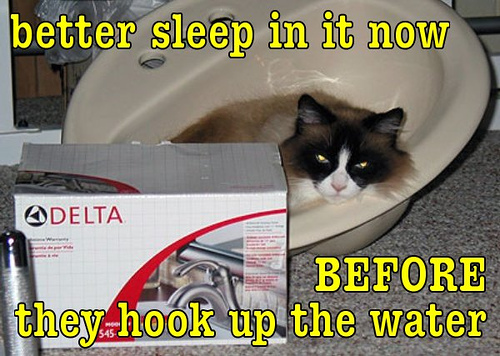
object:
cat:
[166, 91, 420, 206]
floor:
[1, 128, 498, 354]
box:
[13, 139, 293, 349]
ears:
[360, 106, 406, 132]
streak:
[335, 142, 354, 169]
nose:
[330, 170, 349, 193]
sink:
[60, 1, 495, 257]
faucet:
[165, 281, 229, 324]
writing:
[10, 10, 139, 54]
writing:
[49, 204, 124, 226]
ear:
[294, 91, 335, 125]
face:
[298, 129, 387, 204]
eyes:
[313, 153, 333, 164]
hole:
[208, 10, 234, 24]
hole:
[139, 50, 167, 70]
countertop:
[0, 131, 499, 356]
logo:
[23, 204, 49, 228]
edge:
[290, 94, 492, 253]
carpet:
[0, 130, 498, 356]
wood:
[10, 52, 40, 99]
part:
[3, 125, 47, 143]